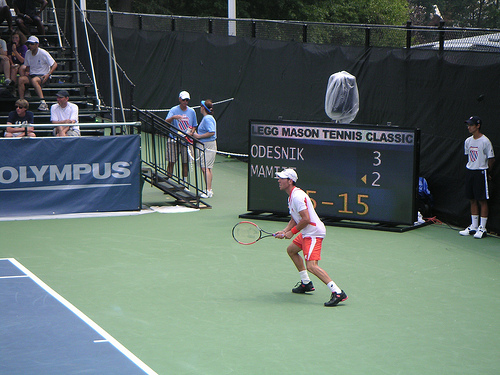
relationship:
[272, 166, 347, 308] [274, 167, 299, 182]
man wearing hat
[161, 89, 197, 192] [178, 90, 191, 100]
man wearing hat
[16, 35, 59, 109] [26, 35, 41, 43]
man wearing hat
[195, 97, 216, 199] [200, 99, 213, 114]
woman wearing visor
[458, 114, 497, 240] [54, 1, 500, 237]
man standing against wall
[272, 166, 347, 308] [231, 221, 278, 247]
man holding tennis racket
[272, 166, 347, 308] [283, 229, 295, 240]
man has hand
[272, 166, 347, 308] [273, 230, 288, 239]
man has hand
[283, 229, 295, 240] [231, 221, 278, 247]
hand holding tennis racket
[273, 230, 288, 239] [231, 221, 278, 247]
hand holding tennis racket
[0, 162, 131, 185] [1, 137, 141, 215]
olympus written on sign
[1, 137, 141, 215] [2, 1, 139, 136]
sign attached to stands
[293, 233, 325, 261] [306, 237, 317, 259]
shorts have stripe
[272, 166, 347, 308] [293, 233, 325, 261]
man wearing shorts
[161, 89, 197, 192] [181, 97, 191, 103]
man wearing sun glasses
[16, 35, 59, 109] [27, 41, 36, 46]
man wearing sun glasses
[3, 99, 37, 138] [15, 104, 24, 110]
man wearing sun glasses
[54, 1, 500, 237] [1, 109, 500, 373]
wall behind court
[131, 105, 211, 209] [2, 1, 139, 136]
stairs leading to stands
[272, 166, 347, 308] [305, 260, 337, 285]
man has skin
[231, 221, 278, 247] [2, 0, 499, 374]
tennis racket shown in scene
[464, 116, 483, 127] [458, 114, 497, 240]
cap worn by man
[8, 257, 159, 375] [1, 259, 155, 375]
line painted on tennis court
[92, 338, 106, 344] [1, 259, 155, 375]
line painted on tennis court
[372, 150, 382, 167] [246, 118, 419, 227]
number 3 shown on score board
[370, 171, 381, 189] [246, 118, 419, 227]
number 2 shown on score board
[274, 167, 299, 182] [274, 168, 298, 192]
hat on top of head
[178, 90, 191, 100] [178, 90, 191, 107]
hat on top of head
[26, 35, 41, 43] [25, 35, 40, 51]
hat on top of head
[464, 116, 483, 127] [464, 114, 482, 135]
cap on top of head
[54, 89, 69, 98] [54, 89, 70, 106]
cap on top of head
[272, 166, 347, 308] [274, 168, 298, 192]
man has head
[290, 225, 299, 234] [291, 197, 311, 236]
wristband around arm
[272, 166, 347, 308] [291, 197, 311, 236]
man has arm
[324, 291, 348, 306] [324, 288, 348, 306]
shoe on foot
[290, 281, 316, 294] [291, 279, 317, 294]
shoe on foot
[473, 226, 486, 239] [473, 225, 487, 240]
shoe on foot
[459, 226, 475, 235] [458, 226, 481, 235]
shoe on foot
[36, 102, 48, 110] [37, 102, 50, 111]
shoe on foot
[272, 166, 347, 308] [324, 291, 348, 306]
man wearing shoe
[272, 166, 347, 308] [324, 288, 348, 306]
man has foot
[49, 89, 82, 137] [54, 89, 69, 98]
man wearing cap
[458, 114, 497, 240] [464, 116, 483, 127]
man wearing cap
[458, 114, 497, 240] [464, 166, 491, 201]
man wearing shorts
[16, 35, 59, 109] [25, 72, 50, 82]
man wearing shorts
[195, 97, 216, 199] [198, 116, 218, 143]
woman wearing blouse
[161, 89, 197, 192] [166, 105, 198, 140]
man wearing shirt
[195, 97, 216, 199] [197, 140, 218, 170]
woman wearing shorts